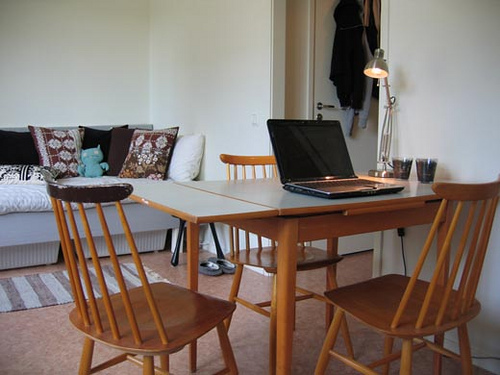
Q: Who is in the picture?
A: No one.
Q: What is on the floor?
A: Rug.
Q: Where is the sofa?
A: On the left.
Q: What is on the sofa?
A: Pillows.